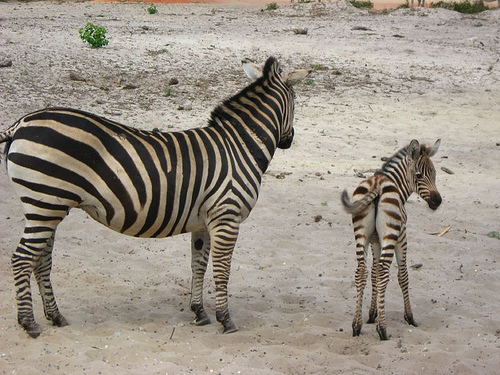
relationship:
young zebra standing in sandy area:
[340, 139, 442, 341] [444, 90, 449, 95]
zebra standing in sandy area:
[0, 58, 294, 339] [444, 90, 449, 95]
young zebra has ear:
[335, 133, 456, 340] [430, 133, 442, 154]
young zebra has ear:
[335, 133, 456, 340] [408, 137, 419, 154]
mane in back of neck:
[207, 51, 284, 129] [218, 79, 283, 164]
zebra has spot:
[0, 58, 294, 339] [192, 233, 205, 253]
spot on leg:
[192, 233, 205, 253] [189, 228, 215, 330]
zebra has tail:
[0, 58, 294, 339] [1, 126, 20, 142]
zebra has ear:
[0, 58, 294, 339] [240, 58, 262, 79]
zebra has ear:
[0, 58, 294, 339] [285, 68, 316, 84]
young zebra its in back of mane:
[340, 139, 442, 341] [377, 136, 419, 171]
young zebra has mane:
[340, 139, 442, 341] [377, 136, 419, 171]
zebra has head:
[0, 58, 294, 339] [265, 60, 300, 146]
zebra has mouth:
[0, 58, 294, 339] [422, 192, 439, 213]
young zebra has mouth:
[340, 139, 442, 341] [422, 192, 439, 213]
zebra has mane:
[0, 58, 294, 339] [215, 54, 275, 121]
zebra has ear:
[0, 58, 294, 339] [280, 66, 312, 84]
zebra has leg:
[0, 58, 294, 339] [190, 233, 217, 327]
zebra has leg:
[0, 58, 294, 339] [32, 254, 72, 328]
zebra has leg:
[0, 58, 294, 339] [7, 217, 52, 338]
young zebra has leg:
[340, 139, 442, 341] [391, 247, 423, 335]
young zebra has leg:
[340, 139, 442, 341] [208, 234, 243, 335]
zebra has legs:
[0, 58, 294, 339] [4, 201, 99, 347]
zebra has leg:
[0, 58, 294, 339] [204, 208, 239, 333]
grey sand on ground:
[0, 0, 500, 375] [1, 2, 497, 373]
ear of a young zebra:
[428, 133, 446, 158] [340, 140, 442, 339]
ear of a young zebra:
[408, 136, 424, 159] [340, 140, 442, 339]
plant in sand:
[77, 21, 105, 56] [26, 24, 225, 99]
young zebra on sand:
[340, 139, 442, 341] [110, 330, 351, 369]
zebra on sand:
[0, 58, 294, 339] [110, 330, 351, 369]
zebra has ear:
[0, 58, 294, 339] [280, 54, 316, 86]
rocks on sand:
[60, 57, 205, 102] [251, 250, 344, 358]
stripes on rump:
[28, 112, 250, 237] [7, 76, 144, 233]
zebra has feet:
[10, 98, 246, 323] [181, 310, 236, 331]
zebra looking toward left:
[0, 58, 294, 339] [2, 8, 254, 371]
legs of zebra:
[11, 213, 67, 335] [0, 58, 294, 339]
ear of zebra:
[236, 58, 260, 83] [0, 58, 294, 339]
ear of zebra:
[286, 67, 310, 84] [0, 58, 294, 339]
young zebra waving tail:
[340, 139, 442, 341] [325, 182, 392, 222]